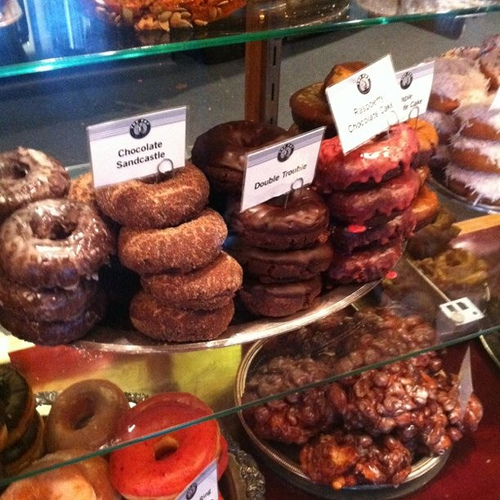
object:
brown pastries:
[96, 168, 211, 227]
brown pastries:
[118, 208, 226, 279]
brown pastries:
[194, 116, 284, 189]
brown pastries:
[147, 257, 247, 312]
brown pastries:
[243, 282, 325, 312]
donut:
[276, 313, 344, 369]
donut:
[358, 334, 442, 388]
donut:
[238, 352, 339, 445]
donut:
[327, 345, 442, 438]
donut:
[396, 364, 486, 457]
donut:
[298, 421, 415, 491]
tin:
[232, 312, 459, 498]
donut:
[33, 374, 136, 450]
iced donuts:
[412, 55, 499, 203]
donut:
[241, 200, 331, 242]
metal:
[221, 339, 496, 494]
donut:
[1, 320, 108, 345]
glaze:
[341, 131, 415, 187]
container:
[84, 243, 447, 491]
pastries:
[313, 355, 430, 437]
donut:
[91, 160, 213, 229]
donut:
[115, 205, 229, 277]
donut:
[139, 249, 244, 309]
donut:
[128, 298, 236, 344]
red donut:
[331, 174, 421, 228]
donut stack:
[193, 110, 420, 306]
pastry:
[0, 360, 48, 477]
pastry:
[5, 451, 119, 500]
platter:
[0, 390, 249, 498]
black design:
[129, 117, 151, 139]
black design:
[277, 142, 295, 160]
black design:
[353, 75, 371, 90]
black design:
[399, 69, 413, 91]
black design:
[184, 482, 197, 497]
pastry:
[90, 153, 215, 228]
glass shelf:
[1, 0, 498, 76]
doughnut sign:
[105, 130, 174, 169]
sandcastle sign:
[88, 102, 189, 189]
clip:
[141, 152, 176, 182]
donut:
[1, 279, 107, 325]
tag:
[243, 127, 329, 209]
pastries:
[228, 187, 337, 321]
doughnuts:
[45, 378, 129, 451]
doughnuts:
[111, 399, 221, 498]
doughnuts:
[320, 121, 415, 189]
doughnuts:
[422, 56, 488, 111]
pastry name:
[107, 140, 168, 170]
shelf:
[4, 219, 486, 401]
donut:
[235, 243, 335, 283]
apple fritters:
[241, 303, 482, 490]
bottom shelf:
[97, 341, 489, 500]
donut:
[236, 277, 324, 318]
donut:
[237, 192, 332, 253]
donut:
[124, 293, 236, 344]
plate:
[75, 243, 411, 356]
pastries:
[188, 118, 295, 195]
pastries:
[290, 80, 336, 135]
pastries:
[1, 143, 66, 215]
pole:
[242, 30, 296, 144]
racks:
[0, 15, 499, 78]